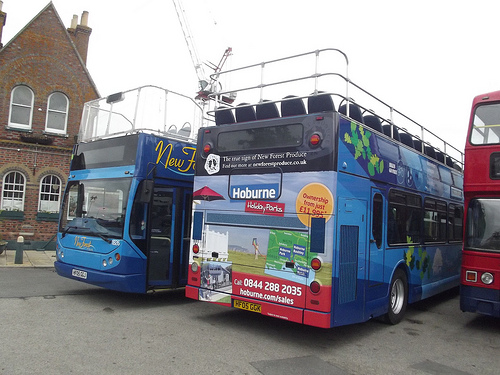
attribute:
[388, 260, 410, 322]
black tire — on bus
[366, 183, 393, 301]
blue door — on back of bus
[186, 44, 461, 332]
bus — blue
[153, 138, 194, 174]
yellow writing — on side of bus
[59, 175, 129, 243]
large windshield — on front of bus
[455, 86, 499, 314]
bus — red, double decker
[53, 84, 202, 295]
bus — blue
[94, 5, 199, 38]
clouds — white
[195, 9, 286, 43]
clouds — white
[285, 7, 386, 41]
clouds — white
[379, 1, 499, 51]
clouds — white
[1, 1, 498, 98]
sky — blue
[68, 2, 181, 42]
clouds — white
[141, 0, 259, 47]
clouds — white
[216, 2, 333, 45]
clouds — white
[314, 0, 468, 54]
clouds — white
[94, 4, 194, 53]
clouds — white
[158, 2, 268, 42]
clouds — white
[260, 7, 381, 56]
clouds — white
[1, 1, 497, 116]
sky — blue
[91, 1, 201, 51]
clouds — white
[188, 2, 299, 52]
clouds — white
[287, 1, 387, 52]
clouds — white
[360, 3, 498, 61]
clouds — white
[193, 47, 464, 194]
top — empty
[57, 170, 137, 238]
windshield — clean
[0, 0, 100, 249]
building — brown, brick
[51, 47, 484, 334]
three buses — parked together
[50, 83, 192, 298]
bus — double deck, red